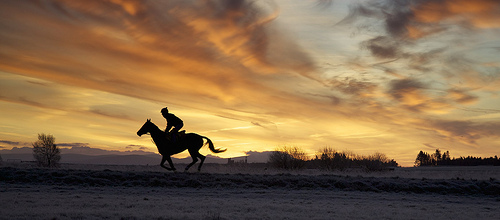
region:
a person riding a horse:
[135, 102, 225, 174]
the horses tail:
[201, 136, 225, 158]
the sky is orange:
[218, 38, 398, 130]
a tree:
[28, 133, 73, 163]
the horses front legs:
[158, 153, 176, 175]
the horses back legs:
[184, 155, 208, 175]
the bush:
[411, 146, 499, 167]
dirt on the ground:
[121, 188, 251, 218]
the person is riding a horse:
[118, 102, 245, 171]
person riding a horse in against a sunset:
[160, 102, 186, 133]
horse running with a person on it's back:
[135, 119, 227, 174]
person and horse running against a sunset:
[134, 106, 228, 176]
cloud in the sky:
[77, 42, 114, 69]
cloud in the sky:
[447, 2, 490, 12]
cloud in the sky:
[413, 2, 440, 18]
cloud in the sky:
[469, 6, 497, 26]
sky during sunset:
[1, 2, 498, 169]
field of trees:
[415, 152, 498, 164]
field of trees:
[267, 151, 396, 170]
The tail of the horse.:
[204, 133, 229, 154]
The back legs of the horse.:
[185, 149, 205, 174]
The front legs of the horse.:
[157, 156, 174, 170]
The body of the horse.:
[155, 131, 203, 153]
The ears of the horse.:
[146, 117, 154, 122]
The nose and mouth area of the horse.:
[135, 128, 144, 137]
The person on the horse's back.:
[153, 106, 187, 131]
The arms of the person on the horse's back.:
[165, 118, 172, 134]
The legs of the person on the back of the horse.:
[169, 126, 187, 131]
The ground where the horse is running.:
[25, 157, 495, 219]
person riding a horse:
[124, 90, 229, 175]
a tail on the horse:
[203, 132, 223, 155]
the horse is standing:
[131, 121, 230, 171]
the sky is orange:
[167, 30, 305, 109]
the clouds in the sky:
[76, 138, 106, 154]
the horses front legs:
[155, 148, 175, 175]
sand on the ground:
[181, 198, 274, 215]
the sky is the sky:
[203, 42, 317, 114]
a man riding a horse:
[79, 61, 305, 185]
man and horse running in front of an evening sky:
[85, 79, 300, 174]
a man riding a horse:
[133, 99, 230, 181]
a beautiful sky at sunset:
[8, 4, 490, 101]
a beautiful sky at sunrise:
[2, 2, 499, 92]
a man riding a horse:
[156, 105, 189, 134]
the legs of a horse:
[156, 148, 208, 178]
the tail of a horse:
[201, 135, 229, 152]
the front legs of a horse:
[155, 153, 175, 178]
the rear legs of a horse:
[182, 150, 206, 175]